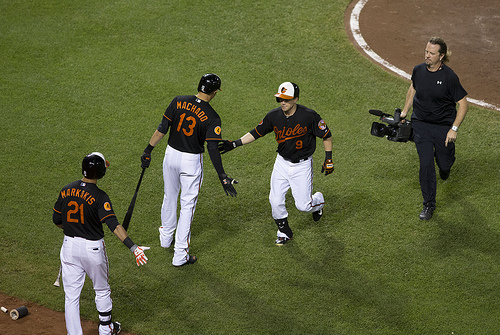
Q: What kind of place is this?
A: It is a field.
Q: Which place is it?
A: It is a field.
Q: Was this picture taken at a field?
A: Yes, it was taken in a field.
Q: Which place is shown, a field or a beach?
A: It is a field.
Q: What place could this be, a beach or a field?
A: It is a field.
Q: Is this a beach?
A: No, it is a field.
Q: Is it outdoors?
A: Yes, it is outdoors.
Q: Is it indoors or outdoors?
A: It is outdoors.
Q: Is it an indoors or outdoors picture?
A: It is outdoors.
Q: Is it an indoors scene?
A: No, it is outdoors.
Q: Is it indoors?
A: No, it is outdoors.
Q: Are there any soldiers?
A: No, there are no soldiers.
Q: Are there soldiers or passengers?
A: No, there are no soldiers or passengers.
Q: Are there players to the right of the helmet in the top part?
A: Yes, there is a player to the right of the helmet.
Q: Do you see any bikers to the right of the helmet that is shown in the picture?
A: No, there is a player to the right of the helmet.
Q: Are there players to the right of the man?
A: Yes, there is a player to the right of the man.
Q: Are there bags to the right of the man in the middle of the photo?
A: No, there is a player to the right of the man.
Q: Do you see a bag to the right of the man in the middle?
A: No, there is a player to the right of the man.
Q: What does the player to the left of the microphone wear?
A: The player wears gloves.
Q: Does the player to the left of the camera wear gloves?
A: Yes, the player wears gloves.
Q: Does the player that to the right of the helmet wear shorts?
A: No, the player wears gloves.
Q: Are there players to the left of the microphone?
A: Yes, there is a player to the left of the microphone.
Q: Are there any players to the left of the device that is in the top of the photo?
A: Yes, there is a player to the left of the microphone.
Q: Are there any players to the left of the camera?
A: Yes, there is a player to the left of the camera.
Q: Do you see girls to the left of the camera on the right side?
A: No, there is a player to the left of the camera.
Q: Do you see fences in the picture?
A: No, there are no fences.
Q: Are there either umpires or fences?
A: No, there are no fences or umpires.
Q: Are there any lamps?
A: No, there are no lamps.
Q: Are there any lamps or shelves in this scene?
A: No, there are no lamps or shelves.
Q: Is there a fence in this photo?
A: No, there are no fences.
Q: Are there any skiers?
A: No, there are no skiers.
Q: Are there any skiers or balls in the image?
A: No, there are no skiers or balls.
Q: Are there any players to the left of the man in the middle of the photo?
A: Yes, there is a player to the left of the man.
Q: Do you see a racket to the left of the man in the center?
A: No, there is a player to the left of the man.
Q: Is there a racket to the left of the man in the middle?
A: No, there is a player to the left of the man.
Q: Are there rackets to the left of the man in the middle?
A: No, there is a player to the left of the man.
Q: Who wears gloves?
A: The player wears gloves.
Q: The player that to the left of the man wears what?
A: The player wears gloves.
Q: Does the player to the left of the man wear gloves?
A: Yes, the player wears gloves.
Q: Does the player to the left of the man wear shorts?
A: No, the player wears gloves.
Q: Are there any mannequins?
A: No, there are no mannequins.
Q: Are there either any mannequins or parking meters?
A: No, there are no mannequins or parking meters.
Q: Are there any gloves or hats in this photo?
A: Yes, there are gloves.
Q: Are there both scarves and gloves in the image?
A: No, there are gloves but no scarves.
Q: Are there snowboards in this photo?
A: No, there are no snowboards.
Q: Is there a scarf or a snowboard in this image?
A: No, there are no snowboards or scarves.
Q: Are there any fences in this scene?
A: No, there are no fences.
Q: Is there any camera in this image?
A: Yes, there is a camera.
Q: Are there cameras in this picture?
A: Yes, there is a camera.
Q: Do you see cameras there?
A: Yes, there is a camera.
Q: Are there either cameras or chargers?
A: Yes, there is a camera.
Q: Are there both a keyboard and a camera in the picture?
A: No, there is a camera but no keyboards.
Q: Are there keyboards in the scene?
A: No, there are no keyboards.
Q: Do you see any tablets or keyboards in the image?
A: No, there are no keyboards or tablets.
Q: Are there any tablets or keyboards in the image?
A: No, there are no keyboards or tablets.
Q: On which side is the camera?
A: The camera is on the right of the image.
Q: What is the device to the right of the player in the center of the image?
A: The device is a camera.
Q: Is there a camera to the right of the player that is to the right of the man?
A: Yes, there is a camera to the right of the player.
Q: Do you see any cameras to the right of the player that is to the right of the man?
A: Yes, there is a camera to the right of the player.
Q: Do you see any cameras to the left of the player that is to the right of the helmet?
A: No, the camera is to the right of the player.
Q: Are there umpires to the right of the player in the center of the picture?
A: No, there is a camera to the right of the player.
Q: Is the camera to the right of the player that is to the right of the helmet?
A: Yes, the camera is to the right of the player.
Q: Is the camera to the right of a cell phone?
A: No, the camera is to the right of the player.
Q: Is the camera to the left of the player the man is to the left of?
A: No, the camera is to the right of the player.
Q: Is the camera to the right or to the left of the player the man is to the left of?
A: The camera is to the right of the player.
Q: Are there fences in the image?
A: No, there are no fences.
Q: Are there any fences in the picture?
A: No, there are no fences.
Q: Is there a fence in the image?
A: No, there are no fences.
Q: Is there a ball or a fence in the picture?
A: No, there are no fences or balls.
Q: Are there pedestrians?
A: No, there are no pedestrians.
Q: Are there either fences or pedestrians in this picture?
A: No, there are no pedestrians or fences.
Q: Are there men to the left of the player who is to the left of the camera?
A: Yes, there is a man to the left of the player.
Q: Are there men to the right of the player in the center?
A: No, the man is to the left of the player.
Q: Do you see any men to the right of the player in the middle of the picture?
A: No, the man is to the left of the player.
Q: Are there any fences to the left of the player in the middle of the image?
A: No, there is a man to the left of the player.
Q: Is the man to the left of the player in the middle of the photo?
A: Yes, the man is to the left of the player.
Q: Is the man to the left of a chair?
A: No, the man is to the left of the player.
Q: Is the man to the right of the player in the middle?
A: No, the man is to the left of the player.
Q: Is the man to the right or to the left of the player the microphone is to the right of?
A: The man is to the left of the player.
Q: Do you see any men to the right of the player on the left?
A: Yes, there is a man to the right of the player.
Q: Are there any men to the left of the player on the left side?
A: No, the man is to the right of the player.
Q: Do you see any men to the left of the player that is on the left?
A: No, the man is to the right of the player.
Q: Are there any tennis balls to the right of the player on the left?
A: No, there is a man to the right of the player.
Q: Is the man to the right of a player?
A: Yes, the man is to the right of a player.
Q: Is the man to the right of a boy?
A: No, the man is to the right of a player.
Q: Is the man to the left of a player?
A: No, the man is to the right of a player.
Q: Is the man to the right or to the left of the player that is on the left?
A: The man is to the right of the player.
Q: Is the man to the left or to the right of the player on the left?
A: The man is to the right of the player.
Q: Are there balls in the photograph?
A: No, there are no balls.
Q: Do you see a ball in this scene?
A: No, there are no balls.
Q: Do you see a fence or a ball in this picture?
A: No, there are no balls or fences.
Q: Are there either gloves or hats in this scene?
A: Yes, there are gloves.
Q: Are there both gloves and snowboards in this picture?
A: No, there are gloves but no snowboards.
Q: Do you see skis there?
A: No, there are no skis.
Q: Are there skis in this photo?
A: No, there are no skis.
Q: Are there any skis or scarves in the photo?
A: No, there are no skis or scarves.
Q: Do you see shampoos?
A: No, there are no shampoos.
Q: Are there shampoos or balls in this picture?
A: No, there are no shampoos or balls.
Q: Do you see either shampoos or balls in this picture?
A: No, there are no shampoos or balls.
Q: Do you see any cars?
A: No, there are no cars.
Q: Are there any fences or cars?
A: No, there are no cars or fences.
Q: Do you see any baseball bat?
A: Yes, there is a baseball bat.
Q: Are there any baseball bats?
A: Yes, there is a baseball bat.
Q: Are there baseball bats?
A: Yes, there is a baseball bat.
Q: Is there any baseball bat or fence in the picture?
A: Yes, there is a baseball bat.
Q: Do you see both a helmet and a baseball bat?
A: Yes, there are both a baseball bat and a helmet.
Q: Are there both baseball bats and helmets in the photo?
A: Yes, there are both a baseball bat and a helmet.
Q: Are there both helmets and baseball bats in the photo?
A: Yes, there are both a baseball bat and a helmet.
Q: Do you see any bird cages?
A: No, there are no bird cages.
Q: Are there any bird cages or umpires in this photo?
A: No, there are no bird cages or umpires.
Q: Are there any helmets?
A: Yes, there is a helmet.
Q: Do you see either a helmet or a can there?
A: Yes, there is a helmet.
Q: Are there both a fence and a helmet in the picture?
A: No, there is a helmet but no fences.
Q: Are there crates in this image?
A: No, there are no crates.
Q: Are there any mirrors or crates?
A: No, there are no crates or mirrors.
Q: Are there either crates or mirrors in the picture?
A: No, there are no crates or mirrors.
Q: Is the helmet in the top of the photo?
A: Yes, the helmet is in the top of the image.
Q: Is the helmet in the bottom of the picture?
A: No, the helmet is in the top of the image.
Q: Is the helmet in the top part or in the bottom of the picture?
A: The helmet is in the top of the image.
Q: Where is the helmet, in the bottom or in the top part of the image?
A: The helmet is in the top of the image.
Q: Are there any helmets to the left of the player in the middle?
A: Yes, there is a helmet to the left of the player.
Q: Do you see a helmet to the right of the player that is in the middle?
A: No, the helmet is to the left of the player.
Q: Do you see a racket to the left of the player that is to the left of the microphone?
A: No, there is a helmet to the left of the player.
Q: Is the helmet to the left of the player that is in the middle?
A: Yes, the helmet is to the left of the player.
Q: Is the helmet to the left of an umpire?
A: No, the helmet is to the left of the player.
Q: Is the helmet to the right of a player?
A: No, the helmet is to the left of a player.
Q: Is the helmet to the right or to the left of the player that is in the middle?
A: The helmet is to the left of the player.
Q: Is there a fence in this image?
A: No, there are no fences.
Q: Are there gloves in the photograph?
A: Yes, there are gloves.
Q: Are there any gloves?
A: Yes, there are gloves.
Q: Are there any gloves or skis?
A: Yes, there are gloves.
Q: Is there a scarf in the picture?
A: No, there are no scarves.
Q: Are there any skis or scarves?
A: No, there are no scarves or skis.